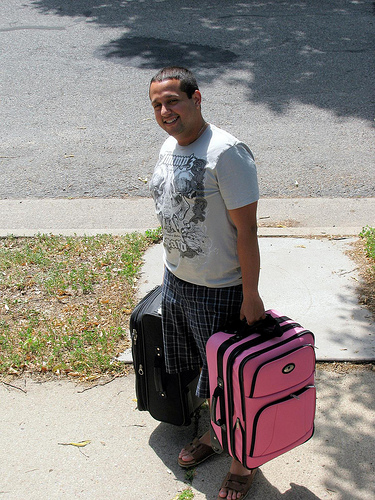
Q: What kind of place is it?
A: It is a sidewalk.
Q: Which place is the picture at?
A: It is at the sidewalk.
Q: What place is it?
A: It is a sidewalk.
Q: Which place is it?
A: It is a sidewalk.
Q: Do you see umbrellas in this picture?
A: No, there are no umbrellas.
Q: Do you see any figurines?
A: No, there are no figurines.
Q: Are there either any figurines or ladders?
A: No, there are no figurines or ladders.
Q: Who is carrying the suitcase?
A: The guy is carrying the suitcase.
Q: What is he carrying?
A: The guy is carrying a suitcase.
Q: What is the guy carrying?
A: The guy is carrying a suitcase.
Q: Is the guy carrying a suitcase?
A: Yes, the guy is carrying a suitcase.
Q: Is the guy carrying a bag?
A: No, the guy is carrying a suitcase.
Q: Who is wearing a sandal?
A: The guy is wearing a sandal.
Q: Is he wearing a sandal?
A: Yes, the guy is wearing a sandal.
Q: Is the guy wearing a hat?
A: No, the guy is wearing a sandal.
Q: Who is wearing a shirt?
A: The guy is wearing a shirt.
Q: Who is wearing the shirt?
A: The guy is wearing a shirt.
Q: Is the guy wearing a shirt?
A: Yes, the guy is wearing a shirt.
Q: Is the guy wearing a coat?
A: No, the guy is wearing a shirt.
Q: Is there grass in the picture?
A: Yes, there is grass.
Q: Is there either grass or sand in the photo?
A: Yes, there is grass.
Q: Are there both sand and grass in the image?
A: No, there is grass but no sand.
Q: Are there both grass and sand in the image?
A: No, there is grass but no sand.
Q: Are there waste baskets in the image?
A: No, there are no waste baskets.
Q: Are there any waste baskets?
A: No, there are no waste baskets.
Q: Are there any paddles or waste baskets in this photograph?
A: No, there are no waste baskets or paddles.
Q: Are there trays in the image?
A: No, there are no trays.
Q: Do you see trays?
A: No, there are no trays.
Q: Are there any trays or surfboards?
A: No, there are no trays or surfboards.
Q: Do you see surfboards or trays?
A: No, there are no trays or surfboards.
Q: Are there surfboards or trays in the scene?
A: No, there are no trays or surfboards.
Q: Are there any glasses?
A: No, there are no glasses.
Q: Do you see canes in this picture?
A: No, there are no canes.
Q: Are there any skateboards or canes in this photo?
A: No, there are no canes or skateboards.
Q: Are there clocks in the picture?
A: No, there are no clocks.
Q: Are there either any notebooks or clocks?
A: No, there are no clocks or notebooks.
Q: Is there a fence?
A: No, there are no fences.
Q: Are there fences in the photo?
A: No, there are no fences.